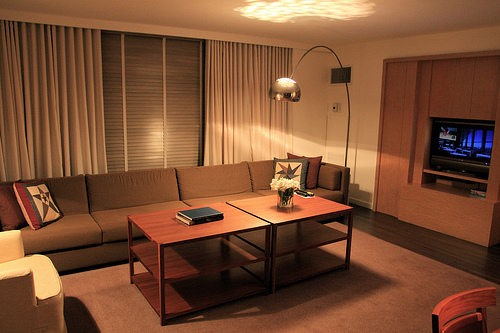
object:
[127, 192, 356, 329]
table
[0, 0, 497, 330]
living room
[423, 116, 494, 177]
television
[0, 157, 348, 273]
couch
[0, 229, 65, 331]
chair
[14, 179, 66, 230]
pillow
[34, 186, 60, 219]
star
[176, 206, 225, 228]
book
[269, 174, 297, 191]
flowers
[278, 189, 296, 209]
pot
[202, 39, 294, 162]
curtains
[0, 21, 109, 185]
curtains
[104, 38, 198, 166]
blinds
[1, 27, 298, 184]
window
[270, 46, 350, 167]
lamp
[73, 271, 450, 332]
carpet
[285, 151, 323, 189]
pillow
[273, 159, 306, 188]
pillow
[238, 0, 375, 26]
reflection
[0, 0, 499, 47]
ceiling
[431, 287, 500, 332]
chair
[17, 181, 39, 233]
trim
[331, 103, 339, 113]
thermostat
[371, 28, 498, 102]
wall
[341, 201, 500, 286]
floor